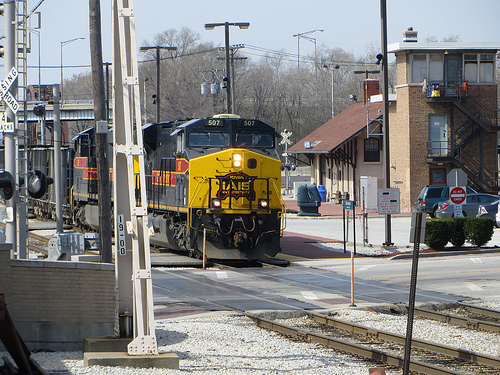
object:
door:
[425, 115, 448, 158]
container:
[315, 183, 326, 201]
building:
[386, 27, 499, 214]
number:
[119, 246, 127, 255]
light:
[233, 153, 244, 162]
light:
[233, 162, 244, 168]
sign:
[376, 187, 398, 215]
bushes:
[423, 215, 455, 249]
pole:
[115, 0, 158, 353]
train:
[0, 113, 297, 262]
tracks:
[249, 315, 500, 375]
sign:
[0, 122, 13, 132]